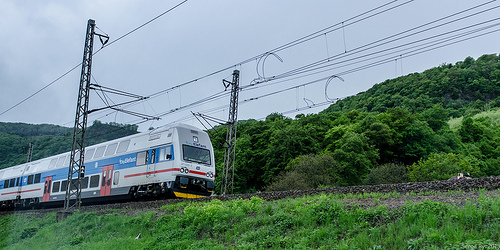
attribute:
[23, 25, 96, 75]
clouds — white, here, faint, covered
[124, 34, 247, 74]
sky — blue, here, white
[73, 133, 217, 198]
train — gray, blue, moving, red, passenger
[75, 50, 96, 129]
post — gray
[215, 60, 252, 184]
towers — metal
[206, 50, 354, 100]
wires — elevated, suspended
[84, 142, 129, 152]
windows — rectangular, different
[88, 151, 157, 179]
stripe — blue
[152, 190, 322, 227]
hill — green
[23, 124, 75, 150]
slope — covered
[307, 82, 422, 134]
vegetation — green